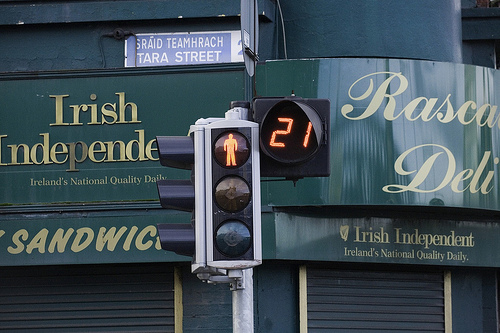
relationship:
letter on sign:
[6, 228, 29, 255] [2, 209, 194, 267]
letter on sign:
[27, 229, 48, 254] [2, 209, 194, 267]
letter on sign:
[46, 227, 74, 252] [2, 209, 194, 267]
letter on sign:
[68, 228, 95, 252] [2, 209, 194, 267]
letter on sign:
[96, 225, 127, 250] [2, 209, 194, 267]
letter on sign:
[124, 225, 140, 250] [2, 209, 194, 267]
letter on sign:
[135, 225, 157, 249] [2, 209, 194, 267]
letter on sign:
[341, 72, 409, 120] [257, 58, 500, 210]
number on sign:
[271, 117, 312, 148] [253, 97, 330, 175]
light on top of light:
[213, 132, 249, 168] [215, 178, 252, 214]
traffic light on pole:
[156, 101, 264, 291] [227, 98, 254, 331]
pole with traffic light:
[227, 98, 254, 331] [156, 101, 264, 291]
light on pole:
[213, 132, 249, 168] [227, 98, 254, 331]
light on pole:
[215, 178, 252, 214] [227, 98, 254, 331]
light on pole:
[214, 221, 253, 258] [227, 98, 254, 331]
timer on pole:
[251, 98, 331, 178] [227, 98, 254, 331]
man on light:
[224, 132, 239, 167] [213, 132, 249, 168]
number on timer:
[271, 117, 312, 148] [251, 98, 331, 178]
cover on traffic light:
[154, 133, 195, 172] [156, 101, 264, 291]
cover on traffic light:
[154, 181, 192, 213] [156, 101, 264, 291]